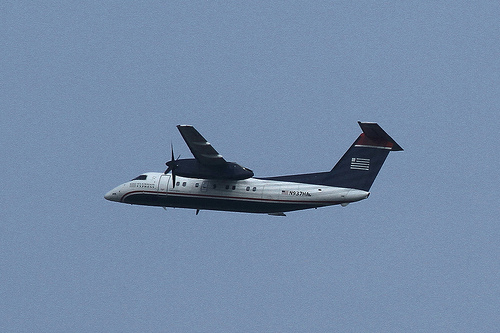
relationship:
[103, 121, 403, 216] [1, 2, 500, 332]
plane flying in sky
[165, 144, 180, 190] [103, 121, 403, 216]
propeller on plane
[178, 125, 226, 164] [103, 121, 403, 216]
wing on side of plane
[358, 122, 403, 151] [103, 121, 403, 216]
rutter on plane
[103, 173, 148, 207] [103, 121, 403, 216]
cockpit of plane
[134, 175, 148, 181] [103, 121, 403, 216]
front window on plane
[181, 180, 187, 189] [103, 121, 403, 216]
window on side of plane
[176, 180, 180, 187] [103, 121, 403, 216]
window on side of plane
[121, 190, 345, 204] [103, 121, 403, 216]
stripe on plane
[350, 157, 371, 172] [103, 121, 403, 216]
flag on back of plane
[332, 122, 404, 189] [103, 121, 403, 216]
tail of plane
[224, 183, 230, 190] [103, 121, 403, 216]
window on plane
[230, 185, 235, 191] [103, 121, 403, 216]
window on plane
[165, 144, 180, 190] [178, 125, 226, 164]
propeller on wing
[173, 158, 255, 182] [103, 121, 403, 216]
engine of plane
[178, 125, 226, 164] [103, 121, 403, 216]
wing of plane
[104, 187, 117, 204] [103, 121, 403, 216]
nose of plane